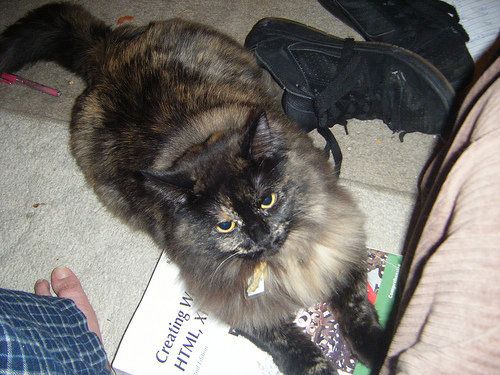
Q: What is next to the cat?
A: Black sneaker.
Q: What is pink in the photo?
A: A pen.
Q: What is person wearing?
A: Blue pajamas.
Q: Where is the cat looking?
A: At camera.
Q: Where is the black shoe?
A: Next to the cat.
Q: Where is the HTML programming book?
A: Under the cat.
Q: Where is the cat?
A: On the floor.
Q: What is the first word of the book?
A: Creating.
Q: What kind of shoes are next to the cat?
A: Black athletic shoes.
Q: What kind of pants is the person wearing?
A: Plaid pajama pants.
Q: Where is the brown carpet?
A: On the floor.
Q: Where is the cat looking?
A: Straight ahead.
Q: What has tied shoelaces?
A: The black sneaker.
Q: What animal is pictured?
A: A cat.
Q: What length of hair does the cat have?
A: Long hair.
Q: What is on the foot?
A: A blue pair of pants.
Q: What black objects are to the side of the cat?
A: Tennis shoes.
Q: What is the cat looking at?
A: The camera.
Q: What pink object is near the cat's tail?
A: A pen.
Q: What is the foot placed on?
A: A carpet.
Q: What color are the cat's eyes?
A: Yellow.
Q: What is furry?
A: A cat.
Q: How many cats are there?
A: One.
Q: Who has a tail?
A: The cat.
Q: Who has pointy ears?
A: Cat.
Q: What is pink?
A: A pen.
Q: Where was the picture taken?
A: On the carpet.